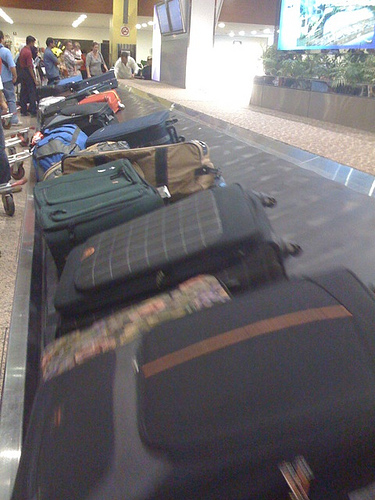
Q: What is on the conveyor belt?
A: Luggage.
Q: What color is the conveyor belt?
A: Black.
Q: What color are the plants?
A: Green.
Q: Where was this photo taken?
A: Airport.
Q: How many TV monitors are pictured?
A: Three.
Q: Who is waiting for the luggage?
A: Passengers.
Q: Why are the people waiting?
A: Waiting for luggage to arrive.